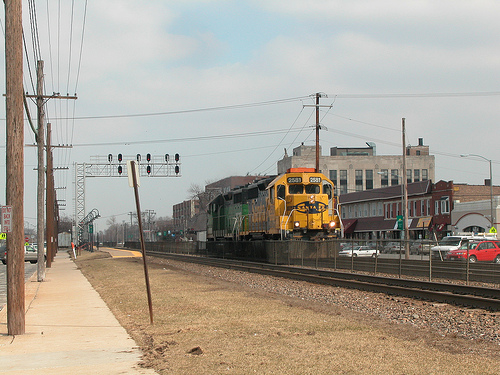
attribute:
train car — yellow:
[215, 170, 356, 275]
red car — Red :
[452, 234, 498, 267]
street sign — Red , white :
[1, 204, 17, 225]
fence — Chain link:
[354, 240, 498, 276]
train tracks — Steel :
[130, 243, 490, 307]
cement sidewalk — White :
[47, 275, 85, 338]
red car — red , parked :
[444, 240, 498, 267]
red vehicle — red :
[450, 232, 498, 267]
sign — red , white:
[0, 202, 16, 232]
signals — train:
[101, 142, 194, 176]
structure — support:
[75, 140, 165, 194]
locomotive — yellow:
[228, 159, 351, 249]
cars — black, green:
[210, 195, 282, 268]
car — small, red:
[440, 219, 492, 272]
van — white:
[418, 221, 479, 269]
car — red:
[465, 228, 487, 278]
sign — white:
[0, 202, 26, 250]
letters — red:
[4, 189, 25, 247]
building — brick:
[349, 160, 439, 232]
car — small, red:
[451, 231, 491, 276]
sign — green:
[388, 214, 428, 238]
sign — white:
[2, 200, 56, 264]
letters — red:
[7, 204, 24, 250]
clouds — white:
[94, 12, 174, 94]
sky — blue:
[183, 19, 265, 64]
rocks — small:
[313, 284, 382, 324]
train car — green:
[180, 190, 295, 264]